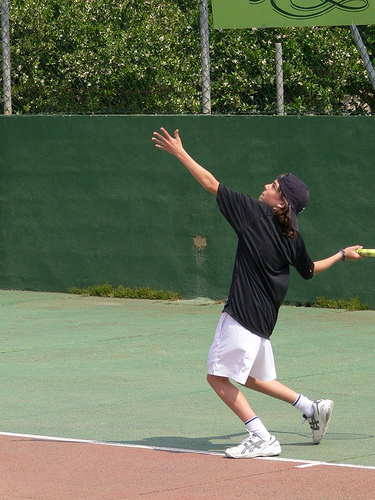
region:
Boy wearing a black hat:
[249, 164, 314, 228]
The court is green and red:
[3, 281, 366, 494]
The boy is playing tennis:
[139, 126, 369, 459]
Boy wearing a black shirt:
[213, 164, 314, 347]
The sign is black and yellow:
[204, 0, 373, 36]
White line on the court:
[0, 403, 371, 483]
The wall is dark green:
[5, 113, 373, 304]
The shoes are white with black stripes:
[217, 395, 340, 461]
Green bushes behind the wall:
[9, 4, 365, 121]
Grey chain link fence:
[2, 3, 360, 114]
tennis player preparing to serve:
[150, 125, 373, 457]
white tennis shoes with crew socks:
[224, 392, 334, 460]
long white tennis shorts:
[205, 310, 278, 383]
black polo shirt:
[215, 180, 317, 342]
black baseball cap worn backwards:
[276, 170, 311, 232]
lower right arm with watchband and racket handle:
[313, 241, 373, 277]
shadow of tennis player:
[105, 436, 319, 457]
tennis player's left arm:
[150, 126, 256, 234]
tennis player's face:
[257, 177, 287, 207]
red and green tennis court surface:
[3, 288, 206, 498]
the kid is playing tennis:
[133, 108, 362, 494]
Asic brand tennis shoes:
[211, 390, 349, 463]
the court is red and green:
[0, 240, 362, 497]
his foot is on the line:
[201, 398, 328, 483]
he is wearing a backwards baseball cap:
[260, 165, 332, 273]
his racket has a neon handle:
[345, 236, 369, 266]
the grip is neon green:
[347, 238, 370, 261]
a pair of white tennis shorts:
[182, 303, 302, 402]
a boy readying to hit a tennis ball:
[107, 68, 344, 461]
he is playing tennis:
[133, 121, 358, 496]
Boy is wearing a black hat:
[143, 126, 365, 453]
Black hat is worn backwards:
[203, 117, 350, 254]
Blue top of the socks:
[218, 373, 330, 453]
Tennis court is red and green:
[5, 266, 373, 497]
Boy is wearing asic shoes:
[207, 386, 344, 483]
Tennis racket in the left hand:
[310, 197, 372, 296]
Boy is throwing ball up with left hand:
[102, 89, 373, 292]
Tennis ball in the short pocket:
[190, 310, 287, 404]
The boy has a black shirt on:
[172, 123, 373, 397]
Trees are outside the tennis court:
[2, 8, 373, 156]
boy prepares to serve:
[164, 104, 365, 491]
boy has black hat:
[266, 158, 330, 227]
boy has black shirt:
[234, 187, 300, 352]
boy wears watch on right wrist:
[333, 232, 352, 276]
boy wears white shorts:
[198, 314, 308, 385]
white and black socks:
[219, 414, 293, 457]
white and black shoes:
[233, 397, 341, 460]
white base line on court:
[32, 421, 374, 491]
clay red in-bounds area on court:
[6, 442, 316, 499]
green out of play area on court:
[52, 297, 166, 414]